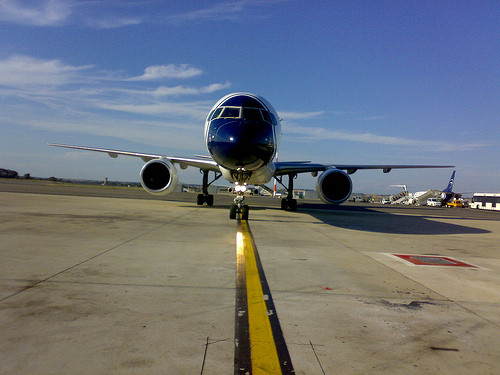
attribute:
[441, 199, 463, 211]
truck — yellow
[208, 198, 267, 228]
wheels — landing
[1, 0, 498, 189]
clouds — White 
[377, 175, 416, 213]
ground — black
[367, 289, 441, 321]
marks — black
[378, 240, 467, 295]
red logo — gray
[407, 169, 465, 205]
airplane — distant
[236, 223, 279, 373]
stripe — yellow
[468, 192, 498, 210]
bus — white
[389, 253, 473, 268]
square — red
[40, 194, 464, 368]
runway — airplane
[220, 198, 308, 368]
line — yellow